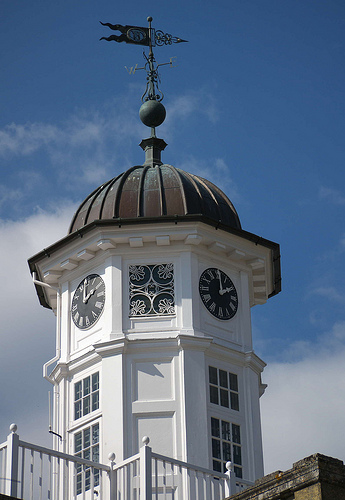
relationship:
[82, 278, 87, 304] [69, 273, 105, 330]
hand of a clock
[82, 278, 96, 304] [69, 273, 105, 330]
hand of a clock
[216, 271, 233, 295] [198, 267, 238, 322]
hand of a clock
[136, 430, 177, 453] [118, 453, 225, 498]
ball on fence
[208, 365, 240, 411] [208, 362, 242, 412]
small/window pane of a window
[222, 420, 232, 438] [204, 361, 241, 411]
small/window pane of a window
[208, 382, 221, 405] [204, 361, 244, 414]
small/window pane of a window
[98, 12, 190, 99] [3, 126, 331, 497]
weather vain on top of a building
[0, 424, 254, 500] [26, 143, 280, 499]
fence around top of building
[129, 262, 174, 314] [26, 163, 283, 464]
decorative pattern on outside of building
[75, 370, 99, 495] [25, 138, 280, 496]
window on top of building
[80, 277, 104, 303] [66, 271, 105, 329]
time on clock clock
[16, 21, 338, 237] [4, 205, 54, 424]
blue sky with clouds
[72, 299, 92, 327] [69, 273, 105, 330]
numerals on clock